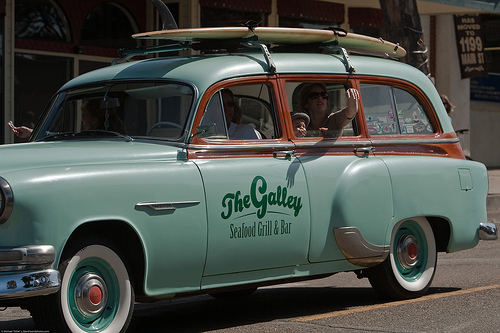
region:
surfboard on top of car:
[117, 14, 410, 61]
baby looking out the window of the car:
[289, 105, 333, 140]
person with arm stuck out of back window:
[304, 86, 371, 142]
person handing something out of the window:
[4, 93, 121, 145]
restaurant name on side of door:
[208, 170, 307, 245]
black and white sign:
[450, 14, 490, 81]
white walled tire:
[57, 240, 150, 330]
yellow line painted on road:
[445, 260, 498, 309]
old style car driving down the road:
[5, 25, 495, 316]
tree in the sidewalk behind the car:
[380, 2, 430, 72]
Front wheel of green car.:
[39, 235, 146, 332]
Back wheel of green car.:
[374, 217, 441, 299]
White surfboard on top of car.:
[130, 23, 409, 57]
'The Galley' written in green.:
[218, 182, 303, 218]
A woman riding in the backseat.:
[306, 83, 357, 139]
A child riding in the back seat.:
[290, 100, 310, 137]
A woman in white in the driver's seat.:
[210, 83, 260, 145]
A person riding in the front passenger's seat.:
[12, 88, 119, 135]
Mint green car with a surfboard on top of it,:
[0, 23, 499, 323]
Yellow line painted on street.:
[287, 278, 498, 327]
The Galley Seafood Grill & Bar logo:
[216, 167, 306, 247]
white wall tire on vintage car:
[31, 233, 142, 332]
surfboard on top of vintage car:
[124, 10, 421, 59]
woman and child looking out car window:
[282, 70, 362, 148]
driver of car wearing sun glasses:
[153, 82, 269, 145]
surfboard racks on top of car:
[256, 42, 362, 72]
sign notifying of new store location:
[448, 6, 498, 86]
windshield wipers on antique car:
[32, 128, 139, 143]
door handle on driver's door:
[269, 146, 305, 160]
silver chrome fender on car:
[0, 238, 59, 303]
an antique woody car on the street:
[3, 3, 498, 323]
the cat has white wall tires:
[52, 215, 439, 331]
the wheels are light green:
[63, 218, 432, 328]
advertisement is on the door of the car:
[212, 165, 307, 253]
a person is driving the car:
[152, 86, 273, 165]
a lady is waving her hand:
[284, 74, 361, 141]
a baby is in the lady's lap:
[288, 82, 357, 139]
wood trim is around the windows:
[181, 63, 465, 165]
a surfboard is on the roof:
[113, 17, 417, 84]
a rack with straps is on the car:
[187, 23, 357, 73]